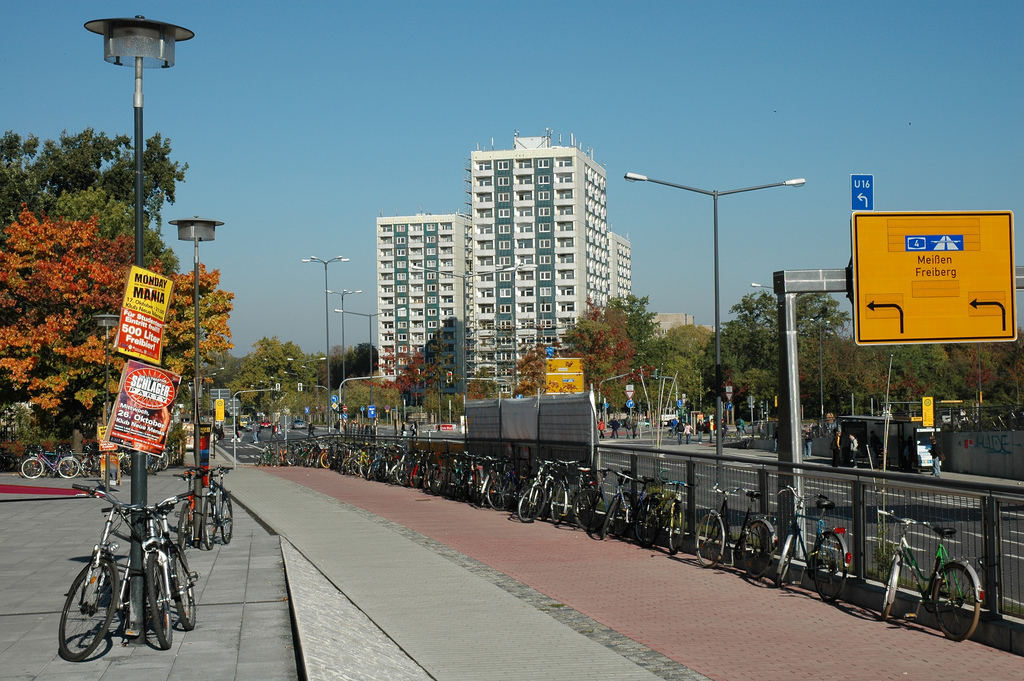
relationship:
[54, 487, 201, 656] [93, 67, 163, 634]
bikes tethered to pole